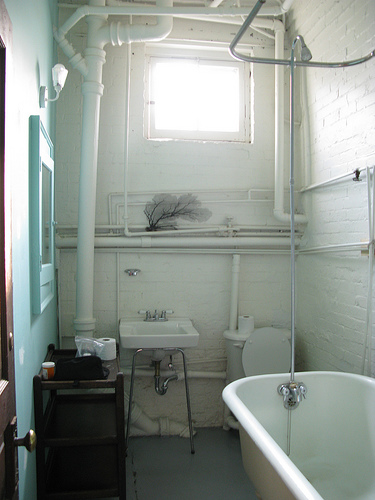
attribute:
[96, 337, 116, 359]
toilet paper — in roll,  white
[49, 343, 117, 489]
shelf —  dark,  wood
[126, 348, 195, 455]
legs —  Metal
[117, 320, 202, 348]
sink — white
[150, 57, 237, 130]
window —  Square,  bathroom's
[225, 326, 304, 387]
toilet —  white 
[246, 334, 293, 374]
lid —  up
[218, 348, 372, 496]
bathtub —  white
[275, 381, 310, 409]
faucet —  Silver,  bathtub's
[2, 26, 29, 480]
door —  brown